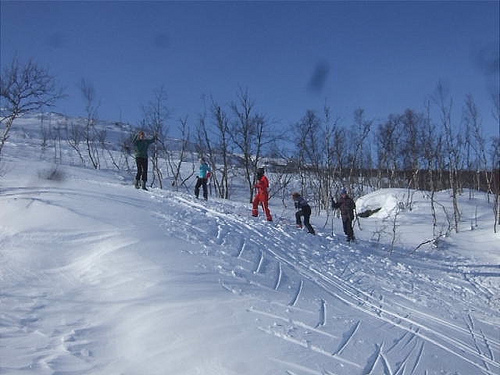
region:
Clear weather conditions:
[198, 18, 263, 61]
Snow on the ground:
[57, 235, 152, 326]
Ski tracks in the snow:
[231, 256, 431, 320]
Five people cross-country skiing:
[128, 123, 370, 248]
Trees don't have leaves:
[333, 113, 454, 168]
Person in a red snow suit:
[251, 166, 271, 220]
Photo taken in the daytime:
[4, 16, 114, 195]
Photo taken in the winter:
[398, 96, 499, 294]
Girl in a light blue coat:
[193, 156, 214, 181]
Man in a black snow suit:
[331, 190, 364, 245]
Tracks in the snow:
[162, 193, 482, 373]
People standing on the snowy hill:
[126, 131, 360, 233]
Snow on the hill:
[3, 150, 498, 370]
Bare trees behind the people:
[166, 106, 498, 223]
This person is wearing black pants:
[193, 177, 210, 202]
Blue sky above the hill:
[1, 1, 499, 171]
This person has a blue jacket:
[193, 159, 213, 179]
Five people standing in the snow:
[127, 135, 362, 238]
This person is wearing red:
[247, 176, 274, 219]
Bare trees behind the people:
[0, 61, 493, 166]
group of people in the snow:
[63, 105, 399, 246]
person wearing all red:
[242, 157, 280, 214]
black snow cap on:
[253, 161, 271, 178]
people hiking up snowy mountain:
[98, 138, 388, 244]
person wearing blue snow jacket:
[190, 157, 212, 175]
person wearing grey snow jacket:
[330, 183, 367, 243]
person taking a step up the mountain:
[272, 180, 318, 248]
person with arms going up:
[118, 125, 169, 185]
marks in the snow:
[205, 231, 310, 340]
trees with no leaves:
[291, 73, 466, 178]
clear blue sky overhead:
[50, 8, 480, 113]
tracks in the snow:
[234, 210, 363, 332]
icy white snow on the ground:
[41, 245, 171, 327]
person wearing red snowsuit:
[249, 166, 280, 239]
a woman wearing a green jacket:
[123, 117, 156, 196]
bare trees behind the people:
[4, 67, 464, 191]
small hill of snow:
[361, 190, 408, 222]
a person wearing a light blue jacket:
[181, 146, 241, 223]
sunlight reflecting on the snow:
[69, 247, 131, 289]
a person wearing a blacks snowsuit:
[330, 185, 358, 240]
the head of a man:
[135, 127, 147, 142]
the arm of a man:
[147, 134, 159, 145]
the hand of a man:
[152, 128, 160, 138]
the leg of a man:
[133, 155, 143, 182]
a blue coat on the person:
[193, 160, 213, 180]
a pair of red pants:
[247, 195, 271, 222]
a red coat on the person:
[251, 175, 274, 200]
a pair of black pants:
[291, 204, 316, 234]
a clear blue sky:
[1, 0, 499, 170]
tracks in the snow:
[163, 189, 499, 374]